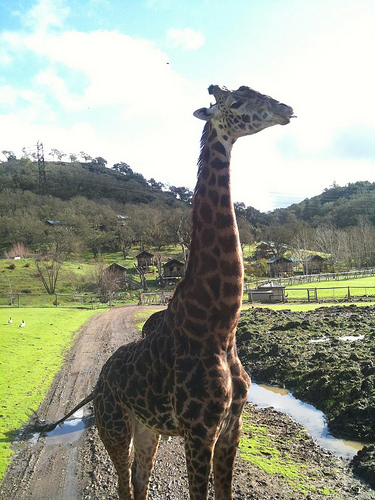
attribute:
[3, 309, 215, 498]
road — dirt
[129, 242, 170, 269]
building — distance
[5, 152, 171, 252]
hillside — tree lined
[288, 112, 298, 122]
tongue — sticking out, Giraffe 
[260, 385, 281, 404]
water — Puddle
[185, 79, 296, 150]
head — giraffe's 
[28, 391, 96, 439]
tail — giraffe's 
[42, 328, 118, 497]
tracks — Vehicle  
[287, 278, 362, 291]
pen — animals 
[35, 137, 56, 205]
pole — Metal utility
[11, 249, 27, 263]
animals — White